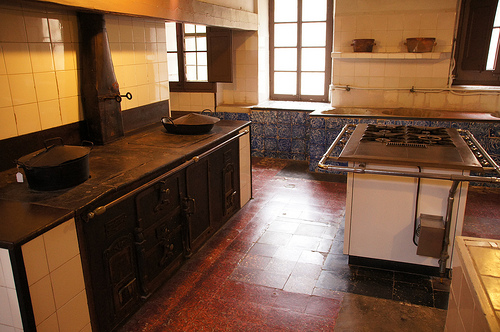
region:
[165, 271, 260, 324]
A brown kitchen floor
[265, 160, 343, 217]
A brown kitchen floor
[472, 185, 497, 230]
A brown kitchen floor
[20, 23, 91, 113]
A white kitchen wall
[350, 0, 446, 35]
A white kitchen wall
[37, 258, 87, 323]
A white kitchen wall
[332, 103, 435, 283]
A big electric cooker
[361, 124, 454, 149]
burners on top of a stove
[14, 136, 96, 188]
a large cast iron pot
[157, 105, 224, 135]
a cast iron wok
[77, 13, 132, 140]
a chimney in a kitchen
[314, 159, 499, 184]
a metal railing on an island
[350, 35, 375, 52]
a cast iron bowl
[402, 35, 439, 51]
a cast iron bowl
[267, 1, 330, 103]
a wooden window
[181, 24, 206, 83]
a window with wooden panes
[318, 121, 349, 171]
railing on an island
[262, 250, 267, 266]
part of a floor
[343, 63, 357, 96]
part of a wall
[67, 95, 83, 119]
edge of a wall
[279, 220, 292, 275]
part of a shadow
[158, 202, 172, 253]
part of a drawer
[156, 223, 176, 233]
part of a handle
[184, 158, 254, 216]
this is a kitchen cabinet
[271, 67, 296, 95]
this is a window pane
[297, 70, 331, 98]
this is a window pane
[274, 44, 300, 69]
this is a window pane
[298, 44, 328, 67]
this is a window pane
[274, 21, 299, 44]
this is a window pane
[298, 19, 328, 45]
this is a window pane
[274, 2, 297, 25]
this is a window pane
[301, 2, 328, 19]
this is a window pane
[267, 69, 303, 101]
Small window in a room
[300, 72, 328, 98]
Small window in a room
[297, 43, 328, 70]
Small window in a room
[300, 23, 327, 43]
Small window in a room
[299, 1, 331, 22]
Small window in a room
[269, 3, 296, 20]
Small window in a room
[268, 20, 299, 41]
Small window in a room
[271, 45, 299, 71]
Small window in a room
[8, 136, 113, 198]
Cast iron skillet on a counter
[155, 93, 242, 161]
Cast iron skillet on a counter